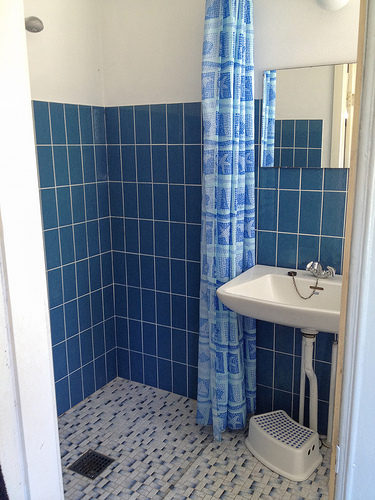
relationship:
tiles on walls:
[31, 100, 348, 437] [24, 0, 349, 438]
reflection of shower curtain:
[261, 69, 277, 167] [196, 0, 256, 443]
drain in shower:
[67, 449, 116, 482] [22, 1, 214, 499]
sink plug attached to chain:
[287, 270, 298, 277] [291, 273, 319, 300]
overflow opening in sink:
[309, 286, 325, 292] [216, 263, 343, 336]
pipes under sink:
[298, 336, 317, 439] [216, 263, 343, 336]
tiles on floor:
[57, 376, 328, 499] [59, 374, 330, 499]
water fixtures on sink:
[304, 261, 335, 277] [216, 263, 343, 336]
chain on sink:
[291, 273, 319, 300] [216, 263, 343, 336]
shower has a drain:
[22, 1, 214, 499] [67, 449, 116, 482]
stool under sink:
[243, 409, 322, 484] [216, 263, 343, 336]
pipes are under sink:
[298, 336, 317, 439] [216, 263, 343, 336]